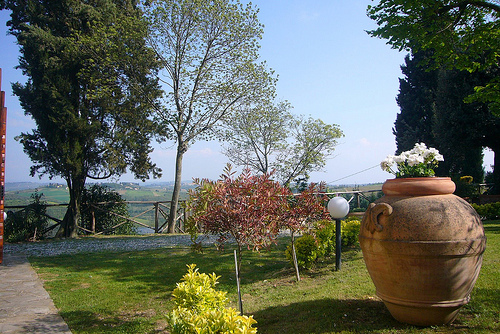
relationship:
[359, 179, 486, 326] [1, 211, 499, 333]
planter on ground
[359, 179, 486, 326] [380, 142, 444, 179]
planter contains flowers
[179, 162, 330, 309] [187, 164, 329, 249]
tree has red leaves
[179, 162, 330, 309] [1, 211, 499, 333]
tree inside garden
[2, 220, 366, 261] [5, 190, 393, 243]
wall under wood fence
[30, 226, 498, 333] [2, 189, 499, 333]
lawn inside garden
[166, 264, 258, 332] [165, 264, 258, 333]
yellow leaves on bush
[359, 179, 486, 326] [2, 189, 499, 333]
planter in garden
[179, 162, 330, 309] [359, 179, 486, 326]
tree near planter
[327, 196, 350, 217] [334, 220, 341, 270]
globe on top of a lightpole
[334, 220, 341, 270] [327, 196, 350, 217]
lightpole under a globe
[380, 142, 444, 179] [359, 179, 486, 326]
flowers inside planter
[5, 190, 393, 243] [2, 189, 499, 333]
wood fence behind garden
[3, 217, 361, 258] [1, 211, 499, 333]
gravel on ground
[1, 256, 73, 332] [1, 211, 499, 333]
concrete on ground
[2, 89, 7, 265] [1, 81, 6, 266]
bricks on building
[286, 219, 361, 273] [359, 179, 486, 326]
bush near planter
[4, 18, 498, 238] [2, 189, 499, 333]
overlook behind garden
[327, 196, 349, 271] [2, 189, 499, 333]
lightpole in garden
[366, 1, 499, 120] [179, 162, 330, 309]
green leaves on a tree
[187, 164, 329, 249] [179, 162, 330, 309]
red leaves on a tree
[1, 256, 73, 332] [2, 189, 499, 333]
pathway on garden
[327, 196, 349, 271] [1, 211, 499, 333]
lightpole attached to ground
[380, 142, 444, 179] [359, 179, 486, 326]
flowers inside a planter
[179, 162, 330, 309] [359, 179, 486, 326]
tree to left of planter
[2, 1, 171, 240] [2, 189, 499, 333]
tree behind garden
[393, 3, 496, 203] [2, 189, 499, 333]
tree behind garden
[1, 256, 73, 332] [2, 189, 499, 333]
concrete to left of garden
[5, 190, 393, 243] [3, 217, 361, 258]
wood fence behind gravel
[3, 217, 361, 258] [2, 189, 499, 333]
gravel behind garden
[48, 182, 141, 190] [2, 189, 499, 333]
homes far behind garden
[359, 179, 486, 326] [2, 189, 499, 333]
planter inside garden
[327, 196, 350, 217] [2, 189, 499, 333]
globe inside garden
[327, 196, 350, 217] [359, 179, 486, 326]
globe behind planter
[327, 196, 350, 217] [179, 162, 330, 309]
globe near tree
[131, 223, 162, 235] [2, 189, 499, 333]
water far behind garden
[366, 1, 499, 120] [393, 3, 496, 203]
leaves on a tree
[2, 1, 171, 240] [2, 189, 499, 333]
tree to left of garden